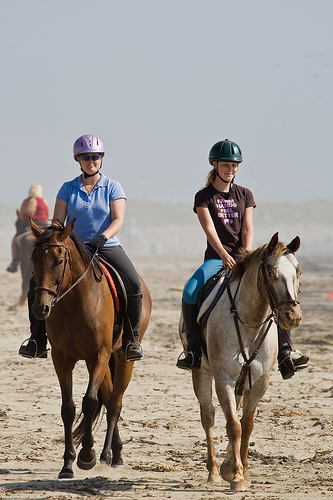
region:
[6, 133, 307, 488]
three people riding horses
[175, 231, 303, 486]
a white and brown horse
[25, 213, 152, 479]
a brown horse with black mane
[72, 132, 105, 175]
a purple riding helmet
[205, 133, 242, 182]
a green riding helmet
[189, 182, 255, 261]
a black t-shirt with pink letters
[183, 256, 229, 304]
a girl wearing blue riding pants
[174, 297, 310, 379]
two black riding boots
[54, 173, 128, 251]
a woman wearing a blue shirt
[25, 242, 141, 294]
a woman wearing black riding pants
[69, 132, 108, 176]
purple helmet with black strap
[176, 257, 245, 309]
blue pants of girl riding horse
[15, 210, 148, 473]
brown horse being ridden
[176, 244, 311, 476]
white horse being ridden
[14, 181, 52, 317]
woman riding away from other woman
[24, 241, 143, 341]
black pants of woman riding brown horse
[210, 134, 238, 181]
helmet of rider with blue pants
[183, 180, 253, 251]
brown shirt with pink lettering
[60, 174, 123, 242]
blue shirt of woman on brown horse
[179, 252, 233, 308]
Girl is wearing blue pants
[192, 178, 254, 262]
Girl is wearing brown shirt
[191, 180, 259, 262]
Brown shirt has pink words on it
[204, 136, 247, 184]
Girl is wearing a green helmet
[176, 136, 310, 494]
Girl is riding a white and brown horse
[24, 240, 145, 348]
Woman is wearing black pants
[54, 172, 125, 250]
Woman is wearing a blue shirt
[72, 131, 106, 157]
Woman is wearing a purple helmet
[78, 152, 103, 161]
Woman is wearing sunglasses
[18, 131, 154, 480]
Woman is riding a brown horse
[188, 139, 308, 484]
Girl riding horse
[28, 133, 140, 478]
woman riding horse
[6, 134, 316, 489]
people riding horses on sandy ground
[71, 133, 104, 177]
person wearing safety helmet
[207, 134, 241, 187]
person wearing safety helmet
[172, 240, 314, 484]
horse is white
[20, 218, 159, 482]
horse is brown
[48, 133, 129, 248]
woman wearing blue polo shirt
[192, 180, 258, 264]
girl wearing brown t-shirt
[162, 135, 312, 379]
girl wearing blue tight pants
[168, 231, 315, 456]
a white and brown horse being ridden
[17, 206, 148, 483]
a brown horse being ridden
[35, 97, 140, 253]
a girl with a purple helmet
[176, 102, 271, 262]
a girl with a green helmet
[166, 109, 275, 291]
a girl with a brown shirt on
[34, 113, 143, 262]
a girl with a blue shirt on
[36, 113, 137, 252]
a girl wearing sunglasses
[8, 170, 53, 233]
a woman with blonde hair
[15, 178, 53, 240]
a woman wearing a red shirt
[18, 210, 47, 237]
the ear of a horse